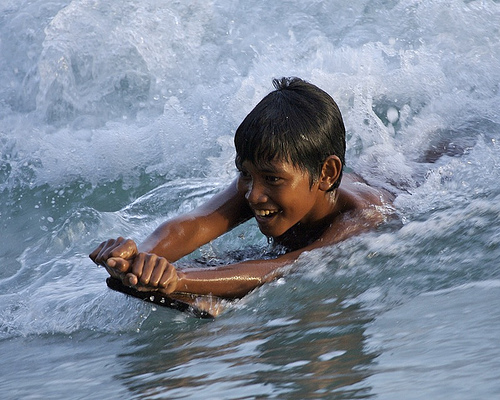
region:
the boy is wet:
[81, 74, 408, 344]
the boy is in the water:
[66, 73, 415, 338]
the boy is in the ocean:
[71, 73, 416, 328]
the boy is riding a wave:
[79, 75, 413, 344]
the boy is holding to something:
[82, 215, 231, 334]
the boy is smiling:
[248, 205, 282, 224]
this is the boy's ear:
[316, 153, 342, 197]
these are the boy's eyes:
[233, 165, 290, 191]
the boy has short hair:
[232, 75, 344, 209]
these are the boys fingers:
[81, 237, 178, 294]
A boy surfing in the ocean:
[54, 63, 471, 379]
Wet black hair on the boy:
[218, 76, 370, 191]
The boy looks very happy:
[234, 95, 349, 235]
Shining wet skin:
[101, 188, 258, 269]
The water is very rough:
[40, 50, 237, 165]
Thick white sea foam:
[342, 52, 456, 121]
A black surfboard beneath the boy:
[85, 278, 215, 338]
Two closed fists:
[82, 234, 180, 294]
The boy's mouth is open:
[245, 199, 281, 226]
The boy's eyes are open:
[230, 164, 291, 189]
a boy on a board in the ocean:
[88, 76, 408, 301]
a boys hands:
[92, 230, 179, 298]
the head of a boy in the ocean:
[226, 76, 347, 233]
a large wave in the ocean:
[2, 1, 497, 398]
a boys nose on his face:
[240, 187, 270, 204]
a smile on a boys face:
[249, 208, 282, 223]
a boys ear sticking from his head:
[323, 156, 343, 194]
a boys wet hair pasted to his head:
[235, 76, 340, 192]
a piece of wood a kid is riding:
[96, 267, 223, 323]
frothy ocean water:
[14, 8, 486, 181]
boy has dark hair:
[250, 88, 313, 164]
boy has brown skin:
[243, 151, 388, 243]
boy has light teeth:
[242, 204, 276, 230]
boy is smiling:
[228, 179, 296, 246]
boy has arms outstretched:
[80, 252, 212, 346]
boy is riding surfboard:
[110, 261, 237, 343]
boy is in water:
[53, 153, 429, 378]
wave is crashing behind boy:
[113, 22, 475, 207]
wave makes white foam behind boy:
[108, 3, 475, 135]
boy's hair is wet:
[231, 53, 367, 201]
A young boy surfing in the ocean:
[24, 28, 481, 387]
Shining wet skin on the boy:
[154, 206, 230, 256]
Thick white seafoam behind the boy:
[56, 15, 184, 129]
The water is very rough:
[396, 64, 486, 345]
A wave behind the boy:
[47, 94, 194, 202]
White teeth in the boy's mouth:
[251, 206, 276, 221]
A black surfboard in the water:
[112, 274, 213, 327]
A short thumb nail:
[102, 251, 117, 271]